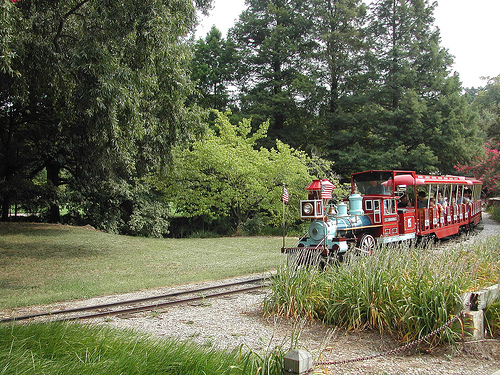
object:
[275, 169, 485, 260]
train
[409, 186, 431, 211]
pasengers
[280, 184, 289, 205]
american flag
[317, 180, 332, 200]
american flag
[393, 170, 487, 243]
carts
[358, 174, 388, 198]
conductor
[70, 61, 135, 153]
branches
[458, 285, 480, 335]
post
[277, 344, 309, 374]
post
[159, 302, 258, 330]
ground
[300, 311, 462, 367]
chain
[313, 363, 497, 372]
path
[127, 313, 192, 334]
gravel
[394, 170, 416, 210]
woman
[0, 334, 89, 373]
grass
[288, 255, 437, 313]
grass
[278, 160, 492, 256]
train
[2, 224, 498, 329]
track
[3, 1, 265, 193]
leaves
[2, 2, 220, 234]
tree